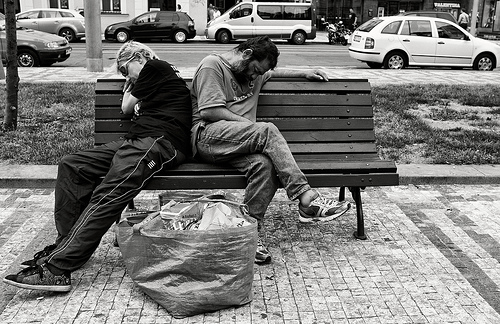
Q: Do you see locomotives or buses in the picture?
A: No, there are no buses or locomotives.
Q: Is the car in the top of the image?
A: Yes, the car is in the top of the image.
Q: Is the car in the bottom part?
A: No, the car is in the top of the image.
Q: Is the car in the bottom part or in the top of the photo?
A: The car is in the top of the image.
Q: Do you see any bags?
A: Yes, there is a bag.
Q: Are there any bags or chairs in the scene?
A: Yes, there is a bag.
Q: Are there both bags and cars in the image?
A: Yes, there are both a bag and a car.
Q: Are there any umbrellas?
A: No, there are no umbrellas.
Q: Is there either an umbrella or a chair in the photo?
A: No, there are no umbrellas or chairs.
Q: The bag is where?
A: The bag is on the ground.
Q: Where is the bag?
A: The bag is on the ground.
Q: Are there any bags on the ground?
A: Yes, there is a bag on the ground.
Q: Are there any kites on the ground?
A: No, there is a bag on the ground.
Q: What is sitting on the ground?
A: The bag is sitting on the ground.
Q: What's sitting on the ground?
A: The bag is sitting on the ground.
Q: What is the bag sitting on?
A: The bag is sitting on the ground.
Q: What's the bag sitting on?
A: The bag is sitting on the ground.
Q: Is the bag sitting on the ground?
A: Yes, the bag is sitting on the ground.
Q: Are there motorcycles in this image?
A: Yes, there is a motorcycle.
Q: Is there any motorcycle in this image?
A: Yes, there is a motorcycle.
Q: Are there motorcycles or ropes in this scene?
A: Yes, there is a motorcycle.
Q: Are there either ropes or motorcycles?
A: Yes, there is a motorcycle.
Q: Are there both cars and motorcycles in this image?
A: Yes, there are both a motorcycle and a car.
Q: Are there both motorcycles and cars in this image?
A: Yes, there are both a motorcycle and a car.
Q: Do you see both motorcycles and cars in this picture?
A: Yes, there are both a motorcycle and a car.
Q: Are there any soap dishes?
A: No, there are no soap dishes.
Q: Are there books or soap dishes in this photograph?
A: No, there are no soap dishes or books.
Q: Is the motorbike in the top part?
A: Yes, the motorbike is in the top of the image.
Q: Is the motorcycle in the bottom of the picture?
A: No, the motorcycle is in the top of the image.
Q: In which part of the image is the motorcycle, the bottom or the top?
A: The motorcycle is in the top of the image.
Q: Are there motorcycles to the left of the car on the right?
A: Yes, there is a motorcycle to the left of the car.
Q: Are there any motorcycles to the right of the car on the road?
A: No, the motorcycle is to the left of the car.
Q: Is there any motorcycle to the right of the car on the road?
A: No, the motorcycle is to the left of the car.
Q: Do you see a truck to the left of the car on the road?
A: No, there is a motorcycle to the left of the car.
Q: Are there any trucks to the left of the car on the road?
A: No, there is a motorcycle to the left of the car.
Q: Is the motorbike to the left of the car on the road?
A: Yes, the motorbike is to the left of the car.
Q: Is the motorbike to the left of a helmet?
A: No, the motorbike is to the left of the car.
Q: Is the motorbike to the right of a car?
A: No, the motorbike is to the left of a car.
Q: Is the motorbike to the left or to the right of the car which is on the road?
A: The motorbike is to the left of the car.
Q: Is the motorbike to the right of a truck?
A: No, the motorbike is to the right of a car.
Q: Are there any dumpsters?
A: No, there are no dumpsters.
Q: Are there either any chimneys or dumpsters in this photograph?
A: No, there are no dumpsters or chimneys.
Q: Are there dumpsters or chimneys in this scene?
A: No, there are no dumpsters or chimneys.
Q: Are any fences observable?
A: No, there are no fences.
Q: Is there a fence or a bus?
A: No, there are no fences or buses.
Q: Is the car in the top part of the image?
A: Yes, the car is in the top of the image.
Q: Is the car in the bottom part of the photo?
A: No, the car is in the top of the image.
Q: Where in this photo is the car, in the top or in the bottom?
A: The car is in the top of the image.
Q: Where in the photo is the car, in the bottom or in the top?
A: The car is in the top of the image.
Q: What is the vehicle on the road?
A: The vehicle is a car.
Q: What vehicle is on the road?
A: The vehicle is a car.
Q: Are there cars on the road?
A: Yes, there is a car on the road.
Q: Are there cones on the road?
A: No, there is a car on the road.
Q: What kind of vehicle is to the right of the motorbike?
A: The vehicle is a car.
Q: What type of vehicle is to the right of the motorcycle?
A: The vehicle is a car.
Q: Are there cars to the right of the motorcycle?
A: Yes, there is a car to the right of the motorcycle.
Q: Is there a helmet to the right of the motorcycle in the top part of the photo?
A: No, there is a car to the right of the motorcycle.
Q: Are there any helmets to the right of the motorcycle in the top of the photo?
A: No, there is a car to the right of the motorcycle.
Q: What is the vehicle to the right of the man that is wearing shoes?
A: The vehicle is a car.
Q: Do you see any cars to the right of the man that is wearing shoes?
A: Yes, there is a car to the right of the man.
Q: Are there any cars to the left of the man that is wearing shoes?
A: No, the car is to the right of the man.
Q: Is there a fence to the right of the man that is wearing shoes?
A: No, there is a car to the right of the man.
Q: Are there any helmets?
A: No, there are no helmets.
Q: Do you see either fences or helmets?
A: No, there are no helmets or fences.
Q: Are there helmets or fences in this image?
A: No, there are no helmets or fences.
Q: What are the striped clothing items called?
A: The clothing items are pants.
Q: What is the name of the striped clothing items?
A: The clothing items are pants.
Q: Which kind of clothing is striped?
A: The clothing is pants.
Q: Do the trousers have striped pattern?
A: Yes, the trousers are striped.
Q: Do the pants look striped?
A: Yes, the pants are striped.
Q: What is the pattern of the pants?
A: The pants are striped.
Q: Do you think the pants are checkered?
A: No, the pants are striped.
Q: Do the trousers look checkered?
A: No, the trousers are striped.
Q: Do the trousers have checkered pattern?
A: No, the trousers are striped.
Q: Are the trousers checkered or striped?
A: The trousers are striped.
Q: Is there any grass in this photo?
A: Yes, there is grass.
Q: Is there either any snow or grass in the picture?
A: Yes, there is grass.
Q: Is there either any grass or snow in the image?
A: Yes, there is grass.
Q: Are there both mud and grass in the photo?
A: No, there is grass but no mud.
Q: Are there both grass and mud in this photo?
A: No, there is grass but no mud.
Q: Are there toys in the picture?
A: No, there are no toys.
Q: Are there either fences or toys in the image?
A: No, there are no toys or fences.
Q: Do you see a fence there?
A: No, there are no fences.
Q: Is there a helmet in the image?
A: No, there are no helmets.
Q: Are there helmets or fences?
A: No, there are no helmets or fences.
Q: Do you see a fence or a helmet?
A: No, there are no helmets or fences.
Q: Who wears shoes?
A: The man wears shoes.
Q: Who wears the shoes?
A: The man wears shoes.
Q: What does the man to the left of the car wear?
A: The man wears shoes.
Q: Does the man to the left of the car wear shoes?
A: Yes, the man wears shoes.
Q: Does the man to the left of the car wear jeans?
A: No, the man wears shoes.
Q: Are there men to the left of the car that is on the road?
A: Yes, there is a man to the left of the car.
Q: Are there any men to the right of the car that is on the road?
A: No, the man is to the left of the car.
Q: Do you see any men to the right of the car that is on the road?
A: No, the man is to the left of the car.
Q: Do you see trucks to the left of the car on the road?
A: No, there is a man to the left of the car.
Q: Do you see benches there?
A: Yes, there is a bench.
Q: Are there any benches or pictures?
A: Yes, there is a bench.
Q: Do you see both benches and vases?
A: No, there is a bench but no vases.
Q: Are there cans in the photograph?
A: No, there are no cans.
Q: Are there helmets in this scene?
A: No, there are no helmets.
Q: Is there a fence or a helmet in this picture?
A: No, there are no helmets or fences.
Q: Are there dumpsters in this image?
A: No, there are no dumpsters.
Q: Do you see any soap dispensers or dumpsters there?
A: No, there are no dumpsters or soap dispensers.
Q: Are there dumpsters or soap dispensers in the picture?
A: No, there are no dumpsters or soap dispensers.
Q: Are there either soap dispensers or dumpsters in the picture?
A: No, there are no dumpsters or soap dispensers.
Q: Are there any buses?
A: No, there are no buses.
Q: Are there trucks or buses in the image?
A: No, there are no buses or trucks.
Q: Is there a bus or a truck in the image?
A: No, there are no buses or trucks.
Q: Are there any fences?
A: No, there are no fences.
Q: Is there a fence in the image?
A: No, there are no fences.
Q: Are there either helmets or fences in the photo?
A: No, there are no fences or helmets.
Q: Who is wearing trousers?
A: The men are wearing trousers.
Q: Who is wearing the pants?
A: The men are wearing trousers.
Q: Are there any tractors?
A: No, there are no tractors.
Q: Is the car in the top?
A: Yes, the car is in the top of the image.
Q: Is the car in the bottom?
A: No, the car is in the top of the image.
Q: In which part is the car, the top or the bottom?
A: The car is in the top of the image.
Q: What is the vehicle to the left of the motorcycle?
A: The vehicle is a car.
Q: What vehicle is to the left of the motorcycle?
A: The vehicle is a car.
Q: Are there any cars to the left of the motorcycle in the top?
A: Yes, there is a car to the left of the motorcycle.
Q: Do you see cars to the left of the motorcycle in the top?
A: Yes, there is a car to the left of the motorcycle.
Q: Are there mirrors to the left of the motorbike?
A: No, there is a car to the left of the motorbike.